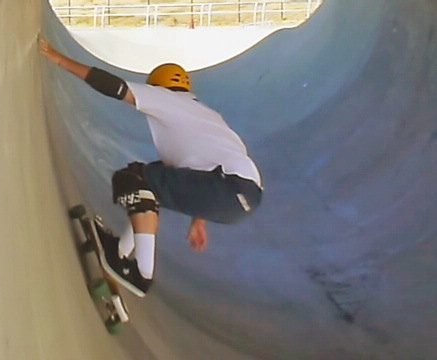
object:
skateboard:
[67, 203, 129, 331]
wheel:
[68, 202, 86, 223]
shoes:
[89, 214, 155, 303]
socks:
[115, 220, 156, 282]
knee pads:
[110, 160, 160, 217]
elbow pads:
[83, 66, 129, 102]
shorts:
[144, 160, 264, 223]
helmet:
[146, 62, 192, 93]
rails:
[54, 2, 312, 27]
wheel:
[88, 279, 109, 299]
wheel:
[103, 315, 128, 336]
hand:
[32, 30, 60, 63]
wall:
[0, 1, 116, 359]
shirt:
[127, 82, 263, 191]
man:
[36, 36, 261, 299]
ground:
[63, 23, 304, 74]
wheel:
[80, 238, 97, 257]